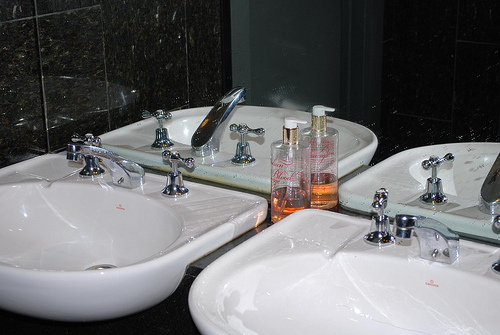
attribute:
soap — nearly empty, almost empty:
[275, 187, 309, 214]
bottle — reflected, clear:
[271, 116, 308, 221]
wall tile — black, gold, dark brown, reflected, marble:
[0, 2, 50, 163]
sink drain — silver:
[86, 263, 115, 277]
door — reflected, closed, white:
[229, 1, 386, 146]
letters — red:
[113, 202, 129, 215]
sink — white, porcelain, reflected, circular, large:
[2, 151, 265, 323]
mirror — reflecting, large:
[32, 2, 500, 252]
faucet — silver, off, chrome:
[82, 144, 143, 186]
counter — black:
[3, 147, 381, 334]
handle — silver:
[159, 148, 194, 200]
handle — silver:
[69, 130, 104, 178]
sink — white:
[187, 199, 498, 335]